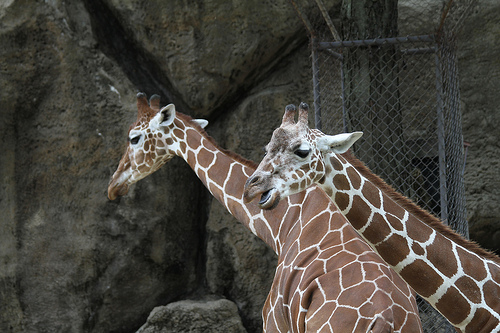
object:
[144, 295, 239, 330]
stone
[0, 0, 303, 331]
stone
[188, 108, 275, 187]
mane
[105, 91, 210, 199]
head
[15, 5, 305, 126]
rocks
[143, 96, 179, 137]
ear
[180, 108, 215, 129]
ear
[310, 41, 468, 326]
fence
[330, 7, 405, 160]
tree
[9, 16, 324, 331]
rock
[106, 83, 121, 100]
spot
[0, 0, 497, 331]
rock pen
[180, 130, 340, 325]
necks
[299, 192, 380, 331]
giraffe's back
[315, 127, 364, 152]
ear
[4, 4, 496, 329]
zoo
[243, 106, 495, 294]
neck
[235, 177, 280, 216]
open mouth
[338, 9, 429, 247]
tree trunk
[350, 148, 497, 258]
hair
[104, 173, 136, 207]
mouth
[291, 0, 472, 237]
silver fence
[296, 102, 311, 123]
horns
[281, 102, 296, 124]
horns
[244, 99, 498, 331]
giraffe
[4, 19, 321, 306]
rock wall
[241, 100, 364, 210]
head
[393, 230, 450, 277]
line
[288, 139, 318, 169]
eye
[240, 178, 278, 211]
mouth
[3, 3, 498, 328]
enclosure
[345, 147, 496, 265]
mane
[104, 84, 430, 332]
giraffe